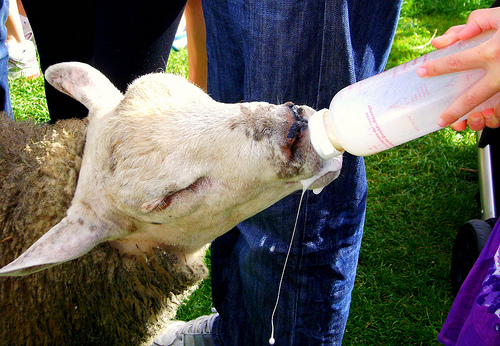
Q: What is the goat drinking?
A: Milk.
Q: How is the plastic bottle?
A: In the goat's mouth.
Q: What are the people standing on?
A: Grass.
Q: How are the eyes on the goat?
A: Closed.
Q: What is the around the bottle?
A: Hands.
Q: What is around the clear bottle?
A: Red letters.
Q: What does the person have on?
A: Blue jeans.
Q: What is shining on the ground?
A: The sun.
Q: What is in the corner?
A: Purple clothing.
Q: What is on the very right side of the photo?
A: Purple clothe.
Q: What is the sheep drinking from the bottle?
A: Milk.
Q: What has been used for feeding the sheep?
A: Milk bottle.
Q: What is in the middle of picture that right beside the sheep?
A: A man with blue jean.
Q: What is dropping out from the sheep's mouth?
A: Milk.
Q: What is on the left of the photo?
A: Black clad legs.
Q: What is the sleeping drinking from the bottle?
A: Milk.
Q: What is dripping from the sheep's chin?
A: Milk.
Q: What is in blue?
A: Jean.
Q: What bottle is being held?
A: Milk.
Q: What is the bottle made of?
A: Plastic.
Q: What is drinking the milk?
A: Sheep.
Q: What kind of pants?
A: Denim.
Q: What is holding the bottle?
A: Hands.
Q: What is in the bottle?
A: Milk.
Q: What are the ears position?
A: Laid back.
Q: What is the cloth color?
A: Purple.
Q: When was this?
A: Daytime.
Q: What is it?
A: A sheep.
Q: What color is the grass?
A: Green.